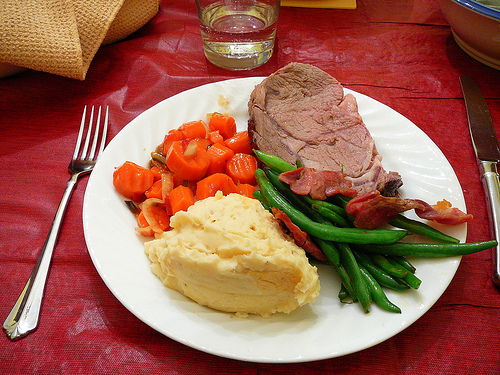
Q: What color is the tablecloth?
A: Red.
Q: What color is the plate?
A: White.